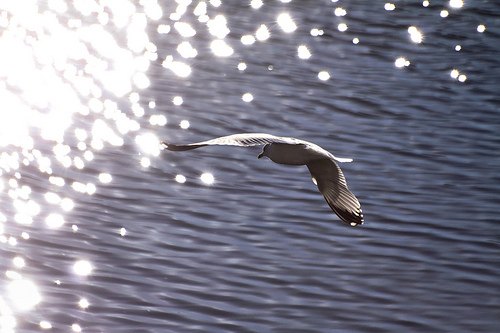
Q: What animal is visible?
A: Bird.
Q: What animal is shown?
A: Seagull.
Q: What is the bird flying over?
A: Water.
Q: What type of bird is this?
A: Seagull.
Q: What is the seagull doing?
A: Flying.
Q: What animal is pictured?
A: Bird.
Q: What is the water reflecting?
A: Sun.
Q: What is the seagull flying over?
A: Water.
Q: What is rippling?
A: Water.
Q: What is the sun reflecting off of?
A: Water.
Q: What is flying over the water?
A: Bird.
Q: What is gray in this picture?
A: Bird.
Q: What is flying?
A: Bird.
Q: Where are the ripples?
A: In the water.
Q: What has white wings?
A: Bird.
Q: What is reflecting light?
A: Water.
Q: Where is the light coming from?
A: Sunlight.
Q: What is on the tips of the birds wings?
A: Black.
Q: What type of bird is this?
A: Seagull.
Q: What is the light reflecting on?
A: Water.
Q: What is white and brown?
A: Seagull.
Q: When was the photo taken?
A: Daytime.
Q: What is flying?
A: Bird.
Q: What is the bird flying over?
A: Water.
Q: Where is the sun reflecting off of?
A: Water.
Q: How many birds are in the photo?
A: One.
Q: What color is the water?
A: Blue.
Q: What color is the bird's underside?
A: White.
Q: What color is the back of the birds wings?
A: Blue.